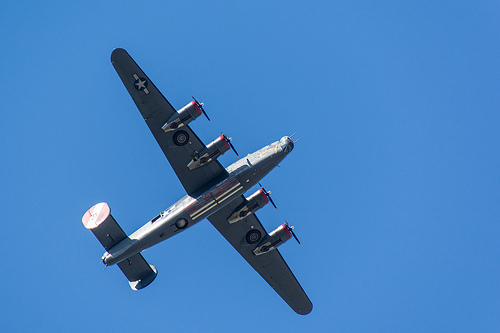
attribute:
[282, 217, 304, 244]
propellar — red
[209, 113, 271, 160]
propeller — red, black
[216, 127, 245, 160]
propeller — black, red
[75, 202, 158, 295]
tail fin — silver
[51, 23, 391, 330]
plane — silver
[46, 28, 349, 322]
jet — silver 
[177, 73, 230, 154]
silver propeller — red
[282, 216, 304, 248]
propeller — black, red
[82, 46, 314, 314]
jet — silver 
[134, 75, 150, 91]
logo —  a star 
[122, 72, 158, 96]
white_star — white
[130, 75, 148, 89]
star — white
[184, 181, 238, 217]
stripe — white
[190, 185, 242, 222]
stripe — white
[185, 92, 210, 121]
propeller — black